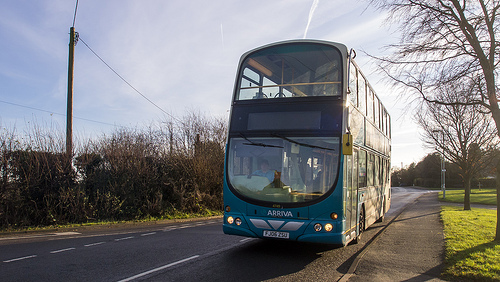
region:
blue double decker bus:
[210, 25, 399, 265]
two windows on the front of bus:
[209, 15, 367, 244]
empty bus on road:
[196, 21, 382, 273]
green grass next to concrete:
[422, 193, 497, 267]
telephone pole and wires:
[42, 7, 182, 230]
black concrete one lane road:
[42, 195, 299, 277]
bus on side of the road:
[79, 26, 464, 271]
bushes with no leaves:
[55, 123, 212, 233]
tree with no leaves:
[417, 34, 482, 183]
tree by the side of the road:
[410, 70, 498, 238]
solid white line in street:
[146, 251, 194, 271]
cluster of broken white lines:
[7, 212, 172, 253]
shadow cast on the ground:
[397, 224, 468, 269]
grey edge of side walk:
[323, 254, 398, 274]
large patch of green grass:
[443, 207, 488, 271]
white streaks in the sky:
[313, 1, 445, 83]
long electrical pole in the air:
[70, 44, 211, 119]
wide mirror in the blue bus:
[198, 104, 355, 216]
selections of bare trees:
[400, 21, 495, 150]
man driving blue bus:
[250, 164, 315, 225]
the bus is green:
[218, 34, 398, 262]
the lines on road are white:
[33, 190, 329, 277]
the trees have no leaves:
[370, 3, 492, 167]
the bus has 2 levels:
[218, 42, 418, 256]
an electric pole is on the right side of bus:
[50, 11, 177, 202]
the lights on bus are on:
[209, 199, 353, 264]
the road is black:
[49, 174, 460, 276]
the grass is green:
[444, 173, 498, 275]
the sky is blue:
[1, 0, 292, 140]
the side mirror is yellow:
[336, 129, 364, 165]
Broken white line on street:
[0, 244, 55, 264]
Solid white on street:
[143, 253, 199, 278]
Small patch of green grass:
[453, 221, 488, 246]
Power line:
[88, 43, 160, 105]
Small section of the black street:
[81, 242, 153, 269]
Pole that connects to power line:
[61, 58, 81, 136]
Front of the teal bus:
[227, 39, 343, 244]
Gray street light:
[433, 128, 448, 198]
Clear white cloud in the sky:
[124, 41, 211, 76]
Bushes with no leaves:
[18, 154, 99, 214]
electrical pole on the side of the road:
[61, 21, 79, 221]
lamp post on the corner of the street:
[436, 124, 450, 199]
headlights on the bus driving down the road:
[225, 214, 244, 228]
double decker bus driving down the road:
[216, 33, 402, 251]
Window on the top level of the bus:
[240, 40, 337, 100]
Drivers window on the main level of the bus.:
[233, 139, 338, 206]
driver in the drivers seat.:
[229, 140, 281, 200]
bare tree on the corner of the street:
[409, 75, 499, 212]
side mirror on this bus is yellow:
[344, 133, 357, 158]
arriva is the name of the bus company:
[257, 205, 299, 218]